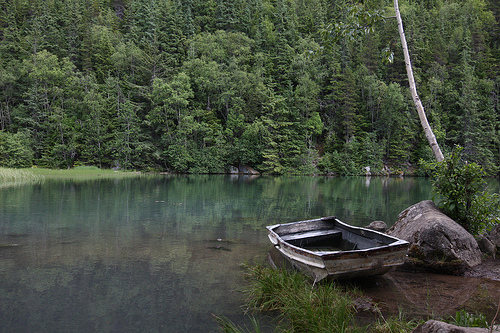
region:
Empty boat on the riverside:
[228, 191, 408, 301]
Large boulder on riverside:
[380, 182, 470, 282]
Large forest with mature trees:
[17, 2, 454, 164]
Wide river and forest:
[5, 0, 497, 329]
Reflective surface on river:
[0, 175, 367, 317]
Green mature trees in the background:
[5, 0, 496, 165]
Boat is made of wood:
[268, 209, 407, 310]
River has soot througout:
[8, 168, 495, 331]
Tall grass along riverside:
[242, 261, 384, 331]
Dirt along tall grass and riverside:
[329, 270, 499, 332]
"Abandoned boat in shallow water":
[176, 156, 443, 284]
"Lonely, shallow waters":
[15, 180, 461, 326]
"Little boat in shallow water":
[27, 162, 474, 302]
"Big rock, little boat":
[251, 186, 492, 306]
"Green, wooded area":
[40, 28, 465, 159]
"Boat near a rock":
[257, 182, 487, 312]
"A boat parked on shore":
[253, 198, 496, 328]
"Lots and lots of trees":
[2, 2, 495, 175]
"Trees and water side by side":
[0, 5, 260, 325]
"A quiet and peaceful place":
[20, 20, 488, 313]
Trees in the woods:
[215, 73, 378, 151]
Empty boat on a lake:
[255, 215, 405, 280]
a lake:
[60, 205, 200, 290]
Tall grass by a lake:
[30, 160, 165, 185]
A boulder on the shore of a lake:
[395, 195, 480, 270]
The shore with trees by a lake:
[110, 140, 305, 185]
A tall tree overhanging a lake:
[360, 10, 455, 165]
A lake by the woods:
[35, 20, 250, 250]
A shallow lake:
[90, 225, 230, 310]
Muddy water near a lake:
[367, 250, 462, 315]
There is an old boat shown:
[259, 210, 413, 292]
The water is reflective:
[0, 170, 499, 332]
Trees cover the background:
[1, 0, 499, 172]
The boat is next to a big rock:
[254, 197, 499, 332]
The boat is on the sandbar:
[0, 212, 499, 330]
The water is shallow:
[1, 222, 279, 332]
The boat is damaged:
[261, 210, 414, 287]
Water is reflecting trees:
[0, 173, 444, 233]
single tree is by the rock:
[388, 0, 473, 255]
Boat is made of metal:
[260, 206, 411, 292]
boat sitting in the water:
[258, 210, 411, 279]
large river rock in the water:
[375, 181, 485, 283]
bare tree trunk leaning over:
[376, 2, 473, 187]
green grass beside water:
[13, 162, 173, 184]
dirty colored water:
[56, 209, 222, 326]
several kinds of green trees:
[66, 12, 266, 144]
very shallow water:
[63, 215, 237, 297]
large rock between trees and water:
[225, 155, 270, 183]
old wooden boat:
[260, 217, 414, 287]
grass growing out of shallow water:
[242, 287, 393, 322]